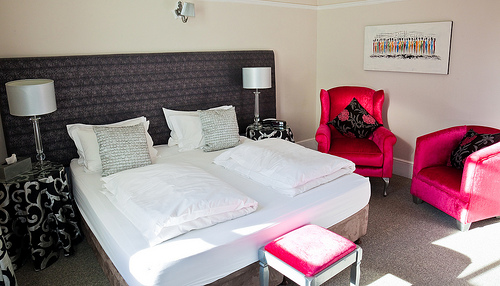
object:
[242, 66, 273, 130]
lamp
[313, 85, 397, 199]
chair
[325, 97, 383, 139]
pillow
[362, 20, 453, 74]
picture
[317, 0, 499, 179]
wall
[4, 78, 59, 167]
lamp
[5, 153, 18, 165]
tissues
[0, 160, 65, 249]
table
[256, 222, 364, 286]
stool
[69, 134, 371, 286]
bed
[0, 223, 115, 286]
carpet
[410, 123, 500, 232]
chair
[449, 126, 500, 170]
pillow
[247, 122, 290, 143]
table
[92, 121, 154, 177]
pillow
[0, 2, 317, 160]
wall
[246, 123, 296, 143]
tablecloth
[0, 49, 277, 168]
headboard